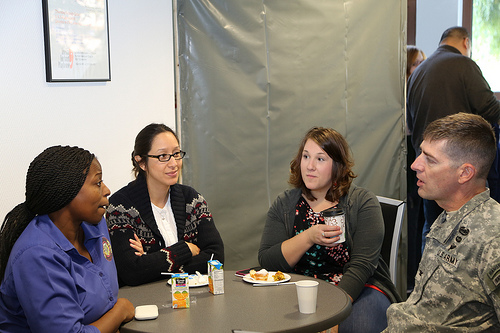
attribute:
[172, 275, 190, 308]
juice carton — here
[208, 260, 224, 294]
juice carton — here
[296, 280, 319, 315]
cup — small, white, paper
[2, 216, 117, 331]
shirt — blue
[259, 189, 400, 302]
shirt — gray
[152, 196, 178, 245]
shirt — white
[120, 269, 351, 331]
table — here, round, gray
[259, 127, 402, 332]
woman — dining, eating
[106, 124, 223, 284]
woman — dining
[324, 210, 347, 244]
cup — gray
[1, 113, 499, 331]
people — conversing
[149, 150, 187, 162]
glasses — black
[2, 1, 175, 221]
wall — white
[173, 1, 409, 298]
plastic — gray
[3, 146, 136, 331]
woman — talking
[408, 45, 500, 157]
shirt — gray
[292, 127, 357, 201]
hair — brown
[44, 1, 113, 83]
picture frame — black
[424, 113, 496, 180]
hair — short